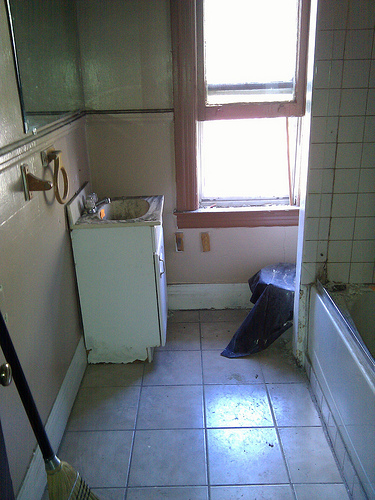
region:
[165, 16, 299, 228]
a large pink window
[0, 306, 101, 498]
a broom with a black handle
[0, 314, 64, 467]
the black handle of the broom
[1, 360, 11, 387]
a shiny door knob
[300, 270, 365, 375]
corner of a dirty bath tub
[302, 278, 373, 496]
a dirty bath tub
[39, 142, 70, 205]
wooden hand towel holder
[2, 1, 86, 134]
rectangular bathroom mirror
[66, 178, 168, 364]
dirty and old bathroom vanity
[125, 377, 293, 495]
dirty tile flooring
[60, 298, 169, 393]
Sink cabinet is deteriorating and moldy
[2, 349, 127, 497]
Broom with dark handle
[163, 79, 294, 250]
Window with pink trim is wide open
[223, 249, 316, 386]
Dark throw over toilet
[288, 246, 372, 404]
Tub surround is moldy and falling apart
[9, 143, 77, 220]
Wooden towel rack on wall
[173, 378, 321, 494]
Floor is shiny tile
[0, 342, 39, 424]
Metal doorknob in front of picture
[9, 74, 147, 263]
Mirror is on wall above sink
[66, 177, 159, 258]
Faucet has two knobs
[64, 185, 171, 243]
Dirty sink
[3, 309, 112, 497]
Broom next to the door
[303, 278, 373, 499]
Bathtub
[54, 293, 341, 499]
Tiled floor of bathroom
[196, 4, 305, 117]
Part of window that slides down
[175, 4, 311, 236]
Entire window frame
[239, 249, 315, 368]
Toilet with black cover on it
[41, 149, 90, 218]
Round hanging towel holder on wall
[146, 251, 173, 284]
Door on sink cabinet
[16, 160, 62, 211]
Hook on the wall next to round towel holder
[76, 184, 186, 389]
sink against wall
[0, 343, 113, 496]
broom on bathroom floor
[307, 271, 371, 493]
edge of bath in bathroom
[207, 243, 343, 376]
blue tarp over toilet seat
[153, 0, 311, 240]
open window at back of room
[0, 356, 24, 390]
doorknob next to the broom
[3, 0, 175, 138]
corner mirror above sink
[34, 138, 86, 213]
towel ring next to sink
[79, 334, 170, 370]
rotten wood on side of sink cabinet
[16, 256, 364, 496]
tiles on bathroom floor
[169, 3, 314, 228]
Open window in a bathroom.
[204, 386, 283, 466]
Bright white spot on a tiled floor.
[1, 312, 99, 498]
Broom with a black handle.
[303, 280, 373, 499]
Dirty bathtub in a bathroom.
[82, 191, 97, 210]
Two clear knobs on a sink.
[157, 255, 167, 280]
Handle on the front of a cabinet.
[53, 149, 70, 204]
Towel holder on the wall.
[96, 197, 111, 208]
silver faucet on a sink.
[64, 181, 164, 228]
Top of a sink basin.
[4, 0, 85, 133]
Mirror hanging on the wall above the sink.